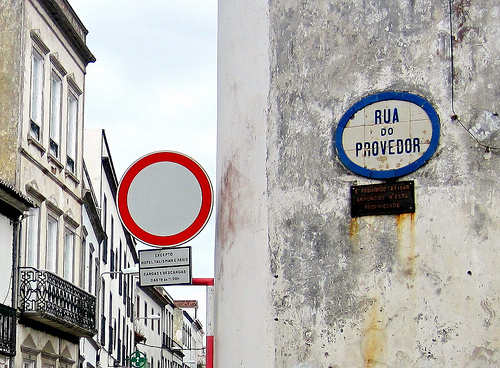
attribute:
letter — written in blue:
[395, 136, 403, 154]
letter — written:
[370, 106, 394, 137]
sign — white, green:
[124, 341, 151, 366]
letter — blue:
[370, 106, 382, 130]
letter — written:
[376, 109, 411, 155]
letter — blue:
[387, 139, 395, 154]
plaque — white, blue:
[320, 82, 435, 177]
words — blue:
[327, 82, 469, 184]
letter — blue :
[358, 136, 375, 168]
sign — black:
[350, 181, 416, 216]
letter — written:
[374, 100, 408, 132]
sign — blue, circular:
[328, 88, 441, 181]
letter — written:
[368, 100, 383, 130]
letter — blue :
[378, 136, 392, 161]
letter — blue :
[371, 138, 381, 156]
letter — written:
[412, 137, 421, 154]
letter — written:
[382, 107, 392, 123]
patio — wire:
[11, 263, 143, 338]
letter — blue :
[404, 135, 421, 157]